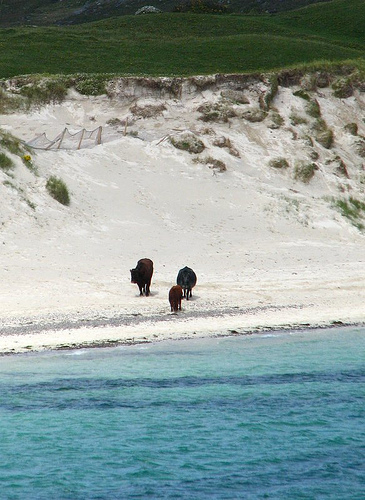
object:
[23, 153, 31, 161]
ball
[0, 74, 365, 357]
hillside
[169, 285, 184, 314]
bison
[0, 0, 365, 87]
plain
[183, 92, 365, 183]
rock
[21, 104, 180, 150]
fence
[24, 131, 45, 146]
post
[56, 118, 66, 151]
post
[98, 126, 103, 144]
post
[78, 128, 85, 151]
post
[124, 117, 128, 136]
post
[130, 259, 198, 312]
three cows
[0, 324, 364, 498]
ocean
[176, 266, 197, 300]
black bison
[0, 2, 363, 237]
grass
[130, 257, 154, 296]
bison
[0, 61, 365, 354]
snow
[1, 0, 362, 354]
ground